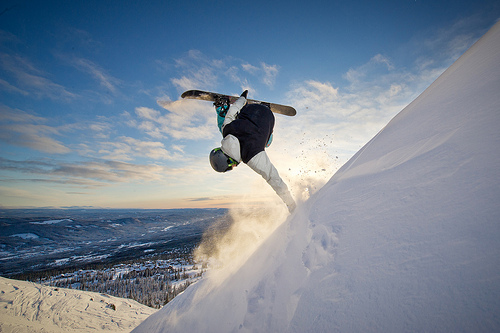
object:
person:
[209, 89, 296, 215]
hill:
[128, 20, 499, 333]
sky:
[0, 3, 498, 209]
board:
[181, 89, 297, 116]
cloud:
[0, 155, 165, 194]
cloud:
[271, 53, 420, 147]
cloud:
[154, 48, 282, 97]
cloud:
[0, 102, 187, 161]